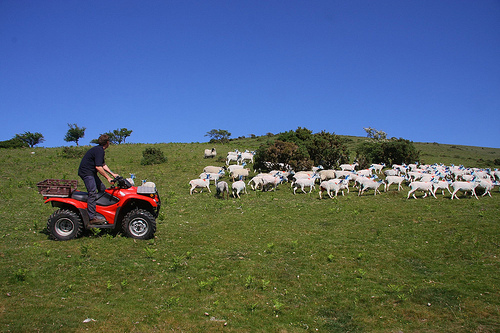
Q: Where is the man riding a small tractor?
A: Farmland.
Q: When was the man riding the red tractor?
A: Workday in the morning.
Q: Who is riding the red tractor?
A: Farm helper.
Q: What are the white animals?
A: Herd of sheep.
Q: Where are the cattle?
A: On ranch land.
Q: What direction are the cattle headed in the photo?
A: East.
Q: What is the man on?
A: Four wheeler.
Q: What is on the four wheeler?
A: A young man.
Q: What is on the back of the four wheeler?
A: A rack.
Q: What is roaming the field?
A: Sheep.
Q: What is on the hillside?
A: Grass.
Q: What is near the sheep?
A: Bushes.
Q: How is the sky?
A: Clear.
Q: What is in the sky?
A: Nothing.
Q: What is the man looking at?
A: Sheep.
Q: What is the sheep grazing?
A: Grass.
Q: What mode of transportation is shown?
A: ATV.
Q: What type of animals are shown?
A: Sheep.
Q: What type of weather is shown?
A: Clear.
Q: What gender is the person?
A: Male.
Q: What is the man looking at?
A: Sheep.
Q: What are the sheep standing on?
A: Grass.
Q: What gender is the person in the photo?
A: Man.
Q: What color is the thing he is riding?
A: Red.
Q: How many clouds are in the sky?
A: None.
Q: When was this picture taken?
A: Daytime.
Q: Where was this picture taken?
A: Green field.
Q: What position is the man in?
A: Standing.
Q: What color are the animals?
A: White.